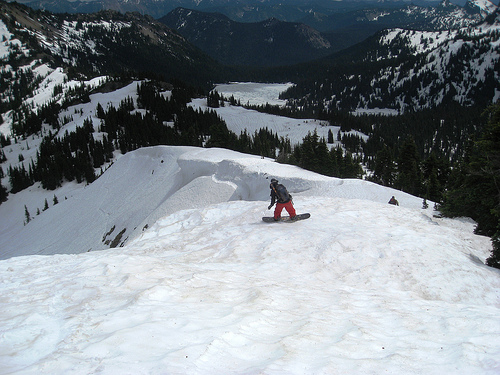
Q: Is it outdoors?
A: Yes, it is outdoors.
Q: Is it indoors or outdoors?
A: It is outdoors.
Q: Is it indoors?
A: No, it is outdoors.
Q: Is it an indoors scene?
A: No, it is outdoors.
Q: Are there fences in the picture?
A: No, there are no fences.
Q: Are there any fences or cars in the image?
A: No, there are no fences or cars.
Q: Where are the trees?
A: The trees are on the mountain.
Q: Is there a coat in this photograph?
A: Yes, there is a coat.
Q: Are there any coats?
A: Yes, there is a coat.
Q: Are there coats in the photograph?
A: Yes, there is a coat.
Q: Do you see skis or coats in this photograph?
A: Yes, there is a coat.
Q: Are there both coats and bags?
A: No, there is a coat but no bags.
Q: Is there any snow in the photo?
A: Yes, there is snow.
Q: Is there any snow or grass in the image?
A: Yes, there is snow.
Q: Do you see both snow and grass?
A: Yes, there are both snow and grass.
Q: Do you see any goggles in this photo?
A: No, there are no goggles.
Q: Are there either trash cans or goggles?
A: No, there are no goggles or trash cans.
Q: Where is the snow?
A: The snow is on the mountain.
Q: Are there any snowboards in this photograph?
A: Yes, there is a snowboard.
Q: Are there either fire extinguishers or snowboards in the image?
A: Yes, there is a snowboard.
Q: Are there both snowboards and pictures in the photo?
A: No, there is a snowboard but no pictures.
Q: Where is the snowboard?
A: The snowboard is on the snow.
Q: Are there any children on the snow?
A: No, there is a snowboard on the snow.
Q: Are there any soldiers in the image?
A: No, there are no soldiers.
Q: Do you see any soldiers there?
A: No, there are no soldiers.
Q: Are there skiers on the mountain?
A: Yes, there is a skier on the mountain.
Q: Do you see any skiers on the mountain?
A: Yes, there is a skier on the mountain.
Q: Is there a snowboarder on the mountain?
A: No, there is a skier on the mountain.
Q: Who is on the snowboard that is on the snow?
A: The skier is on the snowboard.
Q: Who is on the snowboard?
A: The skier is on the snowboard.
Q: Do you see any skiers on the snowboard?
A: Yes, there is a skier on the snowboard.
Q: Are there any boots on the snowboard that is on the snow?
A: No, there is a skier on the snowboard.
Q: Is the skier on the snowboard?
A: Yes, the skier is on the snowboard.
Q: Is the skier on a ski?
A: No, the skier is on the snowboard.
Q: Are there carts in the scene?
A: No, there are no carts.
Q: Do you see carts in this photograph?
A: No, there are no carts.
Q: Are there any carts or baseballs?
A: No, there are no carts or baseballs.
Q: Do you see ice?
A: Yes, there is ice.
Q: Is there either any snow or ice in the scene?
A: Yes, there is ice.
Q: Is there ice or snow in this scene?
A: Yes, there is ice.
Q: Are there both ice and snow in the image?
A: Yes, there are both ice and snow.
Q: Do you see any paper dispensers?
A: No, there are no paper dispensers.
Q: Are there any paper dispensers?
A: No, there are no paper dispensers.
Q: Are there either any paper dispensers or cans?
A: No, there are no paper dispensers or cans.